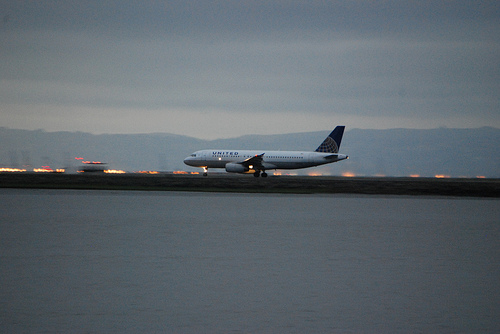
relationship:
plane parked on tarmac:
[181, 123, 352, 181] [278, 173, 376, 184]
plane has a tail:
[181, 123, 352, 181] [313, 125, 350, 158]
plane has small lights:
[181, 123, 352, 181] [238, 154, 255, 164]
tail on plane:
[313, 125, 350, 158] [181, 123, 352, 181]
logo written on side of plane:
[208, 146, 239, 159] [181, 123, 352, 181]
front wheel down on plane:
[200, 167, 213, 179] [181, 123, 352, 181]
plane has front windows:
[181, 123, 352, 181] [187, 151, 200, 162]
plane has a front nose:
[181, 123, 352, 181] [177, 155, 190, 168]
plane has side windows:
[181, 123, 352, 181] [207, 151, 247, 159]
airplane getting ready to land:
[181, 123, 352, 181] [147, 171, 194, 182]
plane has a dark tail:
[181, 123, 352, 181] [313, 125, 350, 158]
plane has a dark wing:
[181, 123, 352, 181] [241, 151, 268, 166]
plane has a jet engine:
[181, 123, 352, 181] [221, 160, 249, 173]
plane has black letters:
[181, 123, 352, 181] [208, 146, 239, 159]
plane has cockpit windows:
[181, 123, 352, 181] [188, 148, 201, 159]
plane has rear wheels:
[181, 123, 352, 181] [250, 169, 274, 181]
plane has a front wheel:
[181, 123, 352, 181] [200, 167, 213, 179]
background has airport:
[131, 150, 177, 169] [0, 157, 500, 180]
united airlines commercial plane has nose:
[181, 123, 352, 181] [177, 155, 190, 168]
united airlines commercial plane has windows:
[181, 123, 352, 181] [266, 152, 306, 166]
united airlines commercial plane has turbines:
[181, 123, 352, 181] [221, 160, 249, 173]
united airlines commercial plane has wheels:
[181, 123, 352, 181] [250, 169, 274, 181]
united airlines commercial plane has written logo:
[181, 123, 352, 181] [208, 146, 239, 159]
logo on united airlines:
[211, 152, 239, 158] [181, 123, 352, 181]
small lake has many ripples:
[93, 205, 405, 283] [134, 238, 245, 286]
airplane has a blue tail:
[181, 123, 352, 181] [313, 125, 350, 158]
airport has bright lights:
[67, 153, 130, 181] [24, 153, 133, 177]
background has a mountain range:
[131, 150, 177, 169] [27, 123, 178, 167]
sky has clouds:
[171, 31, 334, 89] [347, 19, 465, 95]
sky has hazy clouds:
[171, 31, 334, 89] [368, 18, 471, 59]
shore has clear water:
[180, 185, 272, 202] [333, 194, 396, 218]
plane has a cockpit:
[181, 123, 352, 181] [185, 148, 205, 163]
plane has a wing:
[181, 123, 352, 181] [241, 151, 268, 166]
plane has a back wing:
[181, 123, 352, 181] [323, 148, 342, 167]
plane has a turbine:
[181, 123, 352, 181] [221, 160, 249, 173]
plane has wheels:
[181, 123, 352, 181] [250, 169, 274, 181]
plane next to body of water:
[181, 123, 352, 181] [93, 205, 405, 283]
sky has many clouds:
[171, 31, 334, 89] [347, 19, 465, 95]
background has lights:
[131, 150, 177, 169] [334, 167, 462, 183]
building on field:
[69, 159, 115, 180] [113, 171, 160, 180]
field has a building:
[113, 171, 160, 180] [69, 159, 115, 180]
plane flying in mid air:
[181, 123, 352, 181] [298, 32, 454, 88]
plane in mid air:
[181, 123, 352, 181] [298, 32, 454, 88]